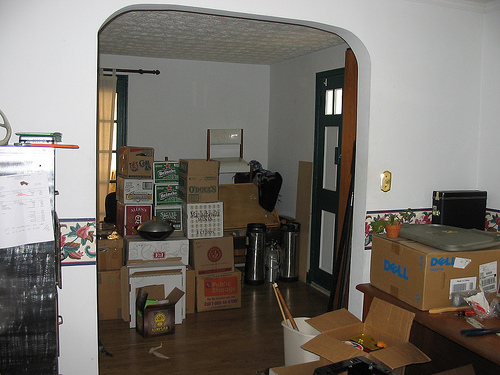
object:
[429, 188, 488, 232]
chest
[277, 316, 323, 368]
cream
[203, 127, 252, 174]
chair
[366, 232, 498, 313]
dell box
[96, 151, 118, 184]
window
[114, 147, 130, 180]
cardboard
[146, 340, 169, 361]
tape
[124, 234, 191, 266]
box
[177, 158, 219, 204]
box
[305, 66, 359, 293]
door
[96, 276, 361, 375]
floor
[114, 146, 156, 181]
box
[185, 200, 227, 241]
box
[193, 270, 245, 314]
box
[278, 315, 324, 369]
bin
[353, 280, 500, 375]
table